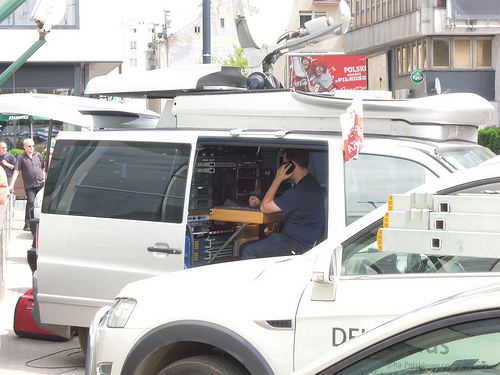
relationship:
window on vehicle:
[34, 141, 181, 227] [37, 130, 499, 327]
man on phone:
[237, 148, 327, 268] [277, 160, 296, 177]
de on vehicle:
[307, 318, 367, 350] [24, 60, 434, 365]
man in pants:
[240, 148, 327, 260] [223, 220, 281, 277]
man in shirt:
[240, 148, 327, 260] [252, 163, 329, 243]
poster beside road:
[286, 52, 371, 94] [18, 189, 290, 369]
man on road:
[1, 119, 50, 237] [0, 224, 35, 299]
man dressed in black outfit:
[240, 148, 327, 260] [238, 171, 323, 259]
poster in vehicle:
[336, 97, 361, 159] [35, 85, 497, 365]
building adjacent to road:
[340, 0, 497, 101] [1, 199, 83, 371]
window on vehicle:
[335, 317, 499, 373] [294, 286, 498, 373]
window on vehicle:
[338, 149, 428, 207] [35, 85, 417, 272]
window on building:
[430, 39, 455, 66] [390, 9, 484, 85]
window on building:
[450, 35, 475, 68] [340, 0, 497, 101]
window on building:
[409, 41, 473, 71] [327, 7, 498, 100]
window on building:
[450, 35, 475, 68] [278, 1, 493, 115]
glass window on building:
[413, 40, 424, 71] [343, 1, 498, 128]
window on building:
[400, 45, 406, 76] [340, 0, 497, 101]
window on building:
[395, 39, 425, 73] [387, 51, 423, 67]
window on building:
[16, 1, 98, 22] [275, 4, 496, 104]